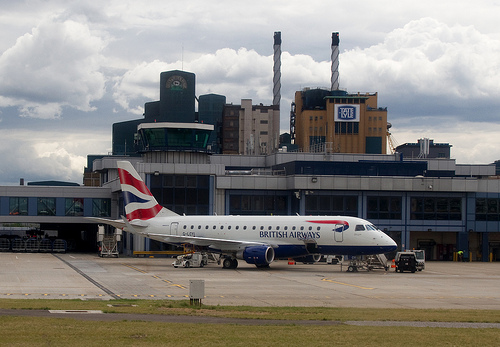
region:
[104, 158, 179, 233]
red and blue design on airplane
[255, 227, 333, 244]
logo on side of airplane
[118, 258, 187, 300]
yellow marking on ground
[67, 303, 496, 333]
sidewalk near airplane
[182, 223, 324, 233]
row of passenger windows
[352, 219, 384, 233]
front windshield for pilot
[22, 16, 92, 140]
dark clouds in sky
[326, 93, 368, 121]
blue and white logo on building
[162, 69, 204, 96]
logo on dark colored building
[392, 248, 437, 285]
car for runway use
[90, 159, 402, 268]
a british airways passenger jet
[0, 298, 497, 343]
a grass strip alongside the runway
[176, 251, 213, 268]
vehicle for loading luggage onto a plane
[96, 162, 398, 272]
a mid-sized jet passenger plane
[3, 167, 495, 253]
a wing of an airport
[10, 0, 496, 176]
a gray sky with large clouds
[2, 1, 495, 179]
a gloomy overcast sky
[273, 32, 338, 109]
smokestacks from an industrial building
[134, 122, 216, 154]
a watchtower guiding planes that are landing and taking off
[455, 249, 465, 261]
an airport crew member wears a neon vest for safety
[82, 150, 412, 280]
airplane parked at the airport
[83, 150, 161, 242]
tail on the white airplane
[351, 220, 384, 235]
windshield of the white airplane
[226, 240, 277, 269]
engine of the white airplane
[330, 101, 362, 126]
white and blue sign on a building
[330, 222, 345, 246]
door of an airplane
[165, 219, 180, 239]
door of an airplane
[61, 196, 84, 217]
large window on a building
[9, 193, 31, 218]
large window on a building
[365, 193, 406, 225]
large window on a building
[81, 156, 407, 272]
A commercial airplane stationed at an airport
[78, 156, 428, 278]
A commercial airplane stationed at an airport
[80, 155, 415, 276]
A commercial airplane stationed at an airport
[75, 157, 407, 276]
A commercial airplane stationed at an airport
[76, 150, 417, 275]
A commercial airplane stationed at an airport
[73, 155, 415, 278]
A commercial airplane stationed at an airport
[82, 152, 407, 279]
A commercial airplane stationed at an airport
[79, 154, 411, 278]
A commercial airplane stationed at an airport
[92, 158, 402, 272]
a red white and blue plane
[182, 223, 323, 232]
windows on a plane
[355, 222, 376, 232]
cockpit windows on a plane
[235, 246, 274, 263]
engine on a plane wing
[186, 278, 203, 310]
a small metal box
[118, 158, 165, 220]
the tail of a plane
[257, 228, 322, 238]
british airways on a plane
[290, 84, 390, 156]
a beige building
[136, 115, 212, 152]
air traffic control center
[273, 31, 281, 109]
a tall smokestack